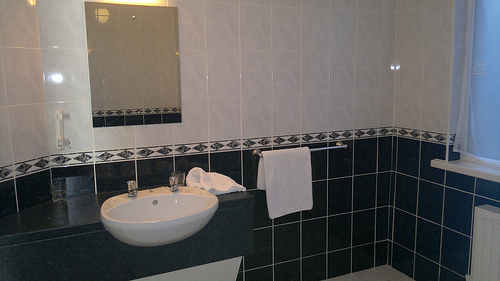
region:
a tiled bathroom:
[1, 3, 498, 280]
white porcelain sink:
[97, 179, 222, 249]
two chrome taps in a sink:
[96, 170, 218, 248]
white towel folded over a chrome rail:
[253, 134, 348, 224]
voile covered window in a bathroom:
[445, 2, 499, 173]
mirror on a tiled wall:
[80, 2, 188, 132]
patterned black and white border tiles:
[4, 126, 461, 183]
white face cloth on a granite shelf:
[183, 161, 248, 198]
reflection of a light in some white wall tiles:
[36, 56, 73, 95]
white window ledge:
[425, 151, 499, 187]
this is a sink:
[111, 194, 209, 241]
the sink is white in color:
[112, 202, 169, 246]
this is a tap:
[166, 171, 181, 187]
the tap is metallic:
[154, 166, 188, 189]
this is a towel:
[266, 151, 319, 211]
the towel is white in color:
[275, 157, 306, 232]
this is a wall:
[226, 18, 361, 100]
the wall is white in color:
[239, 25, 319, 92]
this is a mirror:
[93, 15, 168, 102]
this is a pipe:
[311, 145, 344, 161]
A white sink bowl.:
[97, 170, 218, 250]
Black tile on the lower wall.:
[0, 135, 498, 277]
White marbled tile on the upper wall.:
[2, 0, 447, 170]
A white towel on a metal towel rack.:
[250, 136, 349, 218]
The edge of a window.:
[451, 0, 498, 161]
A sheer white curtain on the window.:
[450, 0, 498, 160]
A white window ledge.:
[427, 150, 497, 185]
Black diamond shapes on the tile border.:
[0, 122, 457, 182]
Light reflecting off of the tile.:
[37, 75, 70, 86]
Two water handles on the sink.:
[119, 171, 184, 196]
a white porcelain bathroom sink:
[99, 183, 218, 246]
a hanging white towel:
[257, 146, 315, 218]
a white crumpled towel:
[185, 167, 247, 194]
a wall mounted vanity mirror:
[82, 0, 183, 127]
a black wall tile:
[352, 173, 376, 213]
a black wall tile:
[329, 174, 352, 218]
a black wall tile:
[327, 210, 351, 252]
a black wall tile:
[351, 207, 376, 249]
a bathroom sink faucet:
[127, 178, 139, 200]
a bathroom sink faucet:
[167, 175, 177, 192]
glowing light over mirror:
[88, 0, 180, 129]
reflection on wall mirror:
[85, 3, 182, 128]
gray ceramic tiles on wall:
[0, 0, 400, 158]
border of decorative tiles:
[48, 125, 393, 167]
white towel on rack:
[254, 139, 347, 219]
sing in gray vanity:
[17, 165, 252, 280]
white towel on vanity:
[183, 165, 255, 199]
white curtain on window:
[449, 1, 498, 171]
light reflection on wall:
[386, 58, 401, 73]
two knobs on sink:
[125, 174, 183, 201]